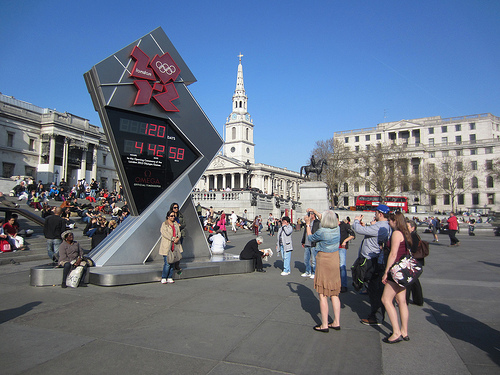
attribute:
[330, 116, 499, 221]
building — gray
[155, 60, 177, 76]
olympic symbol — white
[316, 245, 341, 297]
dress — brown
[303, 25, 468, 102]
sky — blue, clear